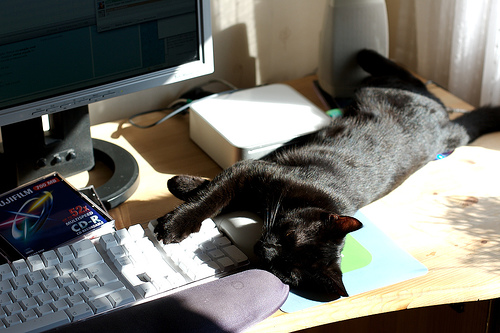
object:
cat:
[153, 48, 498, 302]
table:
[137, 131, 198, 176]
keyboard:
[23, 231, 173, 320]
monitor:
[0, 10, 203, 103]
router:
[202, 92, 306, 148]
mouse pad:
[271, 209, 429, 314]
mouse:
[219, 215, 257, 245]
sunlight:
[181, 61, 213, 75]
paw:
[156, 205, 198, 245]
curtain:
[414, 8, 495, 76]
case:
[12, 190, 100, 239]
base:
[109, 147, 139, 196]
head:
[252, 219, 361, 299]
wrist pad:
[136, 293, 243, 332]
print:
[61, 206, 92, 217]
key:
[59, 274, 68, 285]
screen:
[13, 20, 41, 37]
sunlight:
[359, 194, 461, 250]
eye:
[282, 234, 292, 244]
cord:
[157, 116, 174, 124]